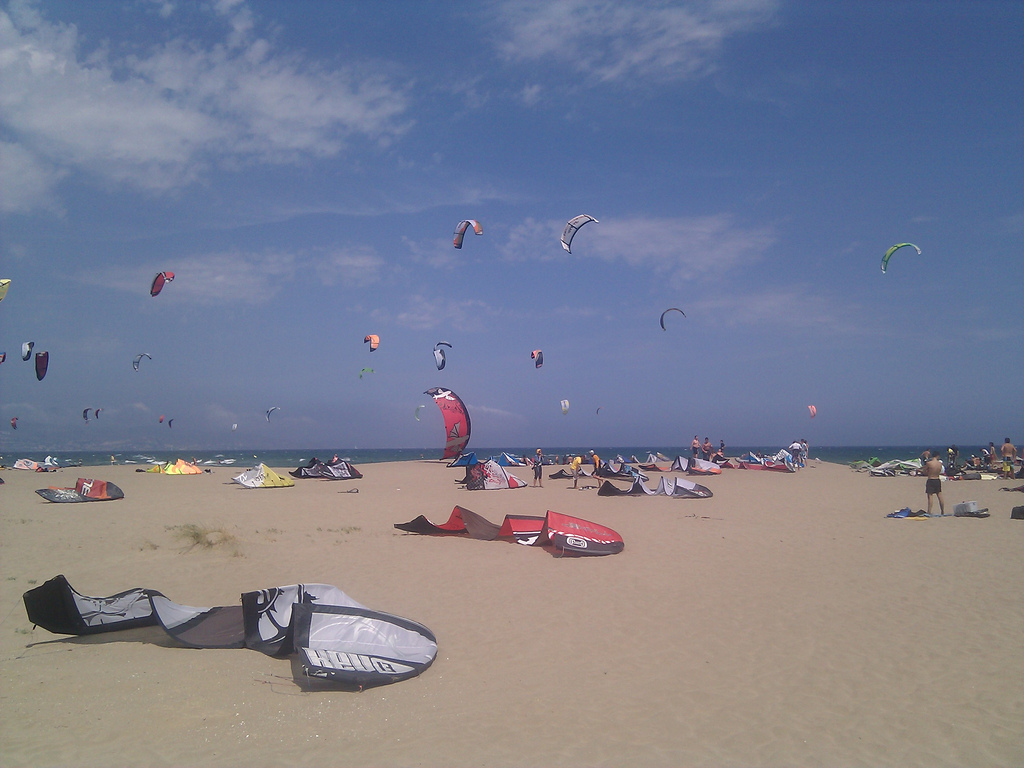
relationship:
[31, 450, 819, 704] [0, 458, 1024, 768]
kites on beach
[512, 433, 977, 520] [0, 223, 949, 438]
people flying kites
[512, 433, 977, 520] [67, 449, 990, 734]
people at beach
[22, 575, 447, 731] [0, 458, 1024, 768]
kite in beach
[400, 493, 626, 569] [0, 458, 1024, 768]
kite in beach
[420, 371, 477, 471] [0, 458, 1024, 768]
kite over beach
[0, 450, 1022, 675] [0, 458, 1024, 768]
kites on beach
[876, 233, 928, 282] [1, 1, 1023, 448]
kite in sky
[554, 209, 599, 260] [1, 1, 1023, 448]
kite in sky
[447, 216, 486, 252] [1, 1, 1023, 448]
kite in sky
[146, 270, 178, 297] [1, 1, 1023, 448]
kite in sky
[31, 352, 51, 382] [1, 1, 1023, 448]
kite in sky